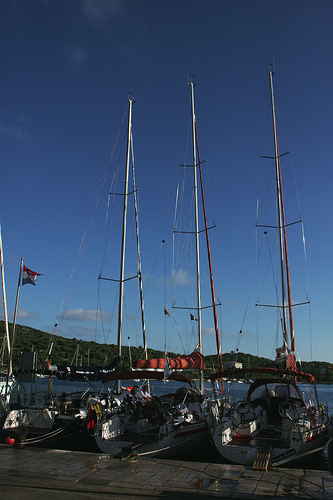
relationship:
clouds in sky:
[0, 0, 332, 365] [0, 0, 332, 363]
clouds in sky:
[61, 300, 110, 328] [0, 0, 332, 363]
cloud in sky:
[0, 16, 326, 365] [0, 0, 332, 363]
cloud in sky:
[63, 307, 110, 322] [0, 0, 332, 363]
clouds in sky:
[3, 1, 252, 347] [0, 0, 332, 363]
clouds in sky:
[0, 0, 332, 365] [1, 0, 329, 254]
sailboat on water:
[212, 69, 330, 462] [7, 375, 330, 411]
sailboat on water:
[1, 47, 228, 461] [7, 375, 330, 411]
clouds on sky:
[3, 1, 252, 347] [1, 2, 332, 318]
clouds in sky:
[0, 0, 332, 365] [2, 2, 331, 207]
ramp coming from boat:
[249, 445, 281, 468] [207, 379, 329, 469]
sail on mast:
[218, 368, 305, 388] [246, 330, 297, 378]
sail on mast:
[111, 369, 202, 387] [176, 333, 195, 378]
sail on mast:
[20, 372, 89, 385] [31, 349, 93, 389]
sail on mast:
[132, 346, 206, 375] [169, 78, 224, 399]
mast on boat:
[112, 89, 133, 393] [92, 351, 228, 454]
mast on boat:
[184, 73, 207, 392] [208, 367, 332, 467]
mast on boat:
[112, 89, 133, 393] [0, 364, 125, 444]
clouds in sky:
[1, 268, 331, 356] [0, 0, 332, 363]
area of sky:
[4, 10, 331, 367] [0, 0, 332, 363]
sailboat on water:
[212, 69, 330, 462] [15, 380, 328, 403]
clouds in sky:
[0, 0, 332, 365] [1, 2, 332, 318]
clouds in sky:
[0, 0, 332, 365] [6, 5, 332, 169]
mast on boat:
[160, 65, 237, 410] [60, 343, 235, 480]